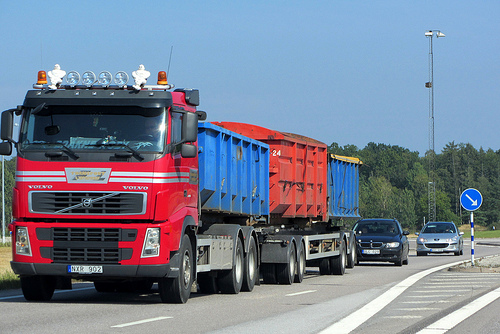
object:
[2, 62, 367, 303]
truck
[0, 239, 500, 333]
road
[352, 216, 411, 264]
car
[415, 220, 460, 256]
car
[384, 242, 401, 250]
front light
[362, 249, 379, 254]
license plate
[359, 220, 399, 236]
windshield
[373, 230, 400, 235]
windshield wiper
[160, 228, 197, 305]
front wheel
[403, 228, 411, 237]
rear view mirror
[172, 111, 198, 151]
rear view mirror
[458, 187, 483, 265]
pole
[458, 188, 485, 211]
sign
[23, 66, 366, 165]
roof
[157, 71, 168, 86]
light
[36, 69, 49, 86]
light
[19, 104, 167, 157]
windshield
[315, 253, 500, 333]
line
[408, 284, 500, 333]
line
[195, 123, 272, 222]
cargo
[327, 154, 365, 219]
cargo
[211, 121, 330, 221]
cargo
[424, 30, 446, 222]
tower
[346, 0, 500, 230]
distance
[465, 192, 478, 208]
arrow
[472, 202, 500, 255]
southeast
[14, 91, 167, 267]
front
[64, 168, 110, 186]
emblem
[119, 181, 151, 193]
volvo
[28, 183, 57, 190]
volvo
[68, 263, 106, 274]
license plate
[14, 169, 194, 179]
stripe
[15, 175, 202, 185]
stripe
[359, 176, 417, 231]
tree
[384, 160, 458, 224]
tree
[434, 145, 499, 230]
tree